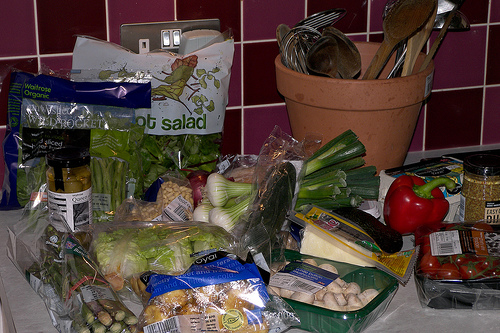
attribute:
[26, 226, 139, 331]
asparagus — green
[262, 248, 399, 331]
mushrooms — tan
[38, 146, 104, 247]
olives — green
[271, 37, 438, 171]
pot — orange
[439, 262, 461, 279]
tomato — red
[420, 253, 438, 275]
tomato — red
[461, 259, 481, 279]
tomato — red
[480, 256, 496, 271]
tomato — red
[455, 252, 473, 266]
tomato — red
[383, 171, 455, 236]
pepper — red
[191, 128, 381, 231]
leeks — green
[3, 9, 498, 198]
wall — tiled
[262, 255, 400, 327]
mushrooms — tan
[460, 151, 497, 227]
condiment — stacked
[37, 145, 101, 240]
condiment — stacked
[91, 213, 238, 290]
lettuce — green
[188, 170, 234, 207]
onion — green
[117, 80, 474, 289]
container — clear